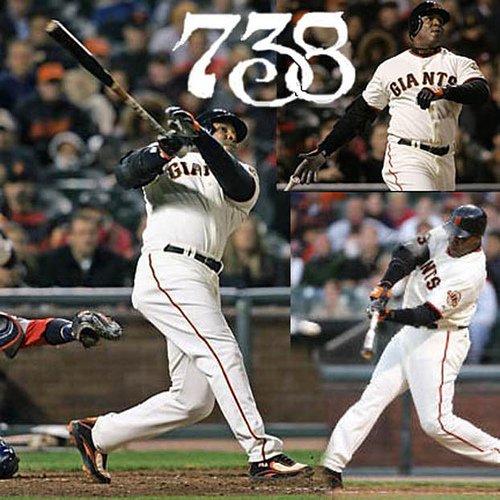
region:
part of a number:
[232, 47, 283, 124]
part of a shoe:
[246, 434, 283, 477]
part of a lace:
[278, 452, 289, 464]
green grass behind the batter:
[12, 444, 322, 469]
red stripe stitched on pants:
[147, 253, 268, 464]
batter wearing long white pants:
[92, 246, 284, 473]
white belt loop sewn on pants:
[182, 243, 196, 259]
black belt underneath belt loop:
[163, 243, 222, 273]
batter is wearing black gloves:
[163, 105, 203, 140]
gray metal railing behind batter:
[0, 285, 134, 307]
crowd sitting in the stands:
[1, 0, 298, 287]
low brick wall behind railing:
[3, 311, 170, 426]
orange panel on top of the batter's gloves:
[368, 285, 382, 297]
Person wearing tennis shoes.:
[55, 409, 279, 499]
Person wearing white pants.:
[143, 253, 262, 433]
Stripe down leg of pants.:
[156, 268, 236, 395]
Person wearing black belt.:
[173, 233, 242, 286]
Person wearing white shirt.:
[171, 208, 231, 238]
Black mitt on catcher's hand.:
[61, 295, 112, 353]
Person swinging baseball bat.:
[363, 269, 406, 353]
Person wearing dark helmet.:
[436, 206, 491, 249]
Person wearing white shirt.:
[416, 253, 471, 318]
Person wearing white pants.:
[357, 333, 466, 418]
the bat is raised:
[25, 18, 201, 155]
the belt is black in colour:
[143, 235, 236, 278]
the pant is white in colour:
[129, 237, 282, 476]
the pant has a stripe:
[131, 258, 256, 475]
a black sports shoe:
[65, 405, 119, 493]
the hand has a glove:
[41, 278, 141, 370]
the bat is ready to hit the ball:
[343, 244, 421, 348]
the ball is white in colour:
[293, 286, 334, 341]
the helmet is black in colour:
[435, 204, 494, 244]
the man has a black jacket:
[38, 206, 140, 286]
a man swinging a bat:
[47, 18, 255, 223]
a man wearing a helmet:
[398, 5, 466, 50]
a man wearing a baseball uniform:
[141, 107, 253, 494]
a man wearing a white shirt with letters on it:
[390, 32, 466, 153]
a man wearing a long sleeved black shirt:
[297, 57, 490, 182]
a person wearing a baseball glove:
[63, 281, 125, 347]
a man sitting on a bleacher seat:
[26, 217, 119, 288]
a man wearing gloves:
[147, 110, 222, 169]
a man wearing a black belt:
[388, 132, 466, 155]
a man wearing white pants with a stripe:
[108, 256, 215, 448]